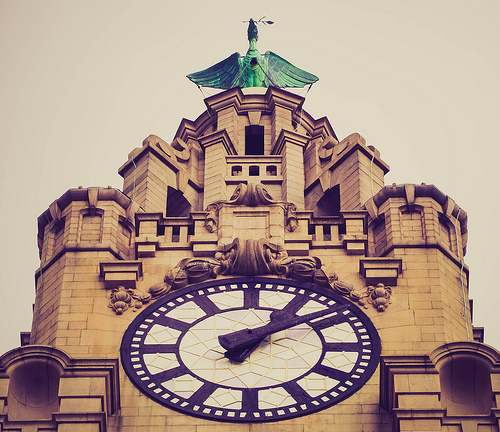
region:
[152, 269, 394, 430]
Clock on the wall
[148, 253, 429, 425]
Clock on a building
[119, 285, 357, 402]
Clock on a building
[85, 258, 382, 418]
The clock is large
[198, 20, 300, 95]
A green statue on top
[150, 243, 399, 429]
the clock reads 2:09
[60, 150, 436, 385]
The building is made of stone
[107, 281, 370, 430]
the clock is white and black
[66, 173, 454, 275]
the building is very decorated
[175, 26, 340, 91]
the statue is a green bird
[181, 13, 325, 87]
The statue is green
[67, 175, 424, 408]
This is a clocktower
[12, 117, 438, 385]
The building looks old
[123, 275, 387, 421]
a black and white clock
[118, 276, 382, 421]
a clock with stripes to represent numbers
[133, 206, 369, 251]
railings on a balcony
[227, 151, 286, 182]
a railing in front of a doorway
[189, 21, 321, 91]
a green winged statue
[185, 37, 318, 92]
a statue on the top of a tower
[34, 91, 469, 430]
a tan colored tower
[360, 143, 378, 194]
a pipe on the side of the tower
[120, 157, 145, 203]
a pipe of the tower's side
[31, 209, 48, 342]
a pipe on the side of a tower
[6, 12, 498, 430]
a clock tower with a verdigris bird on top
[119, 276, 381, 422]
the clock face is white with a gold design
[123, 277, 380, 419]
the number marks and hands are black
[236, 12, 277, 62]
a rose bud is in the bird's mouth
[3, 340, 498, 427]
arches are on both sides of the clock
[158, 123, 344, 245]
open arched windows are on the tower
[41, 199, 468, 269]
closed arched windows are on the sides of the tower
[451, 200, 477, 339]
a steel pipe is on the side of the tower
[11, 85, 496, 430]
parapets are in numerous places on the tower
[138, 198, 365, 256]
a portion of the tower has a balcony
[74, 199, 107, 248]
This is a window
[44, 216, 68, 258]
This is a window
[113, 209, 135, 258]
This is a window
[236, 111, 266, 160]
This is a window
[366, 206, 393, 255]
This is a window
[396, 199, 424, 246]
This is a window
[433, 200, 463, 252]
This is a window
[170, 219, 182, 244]
This is a window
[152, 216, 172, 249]
This is a window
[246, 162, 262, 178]
This is a window